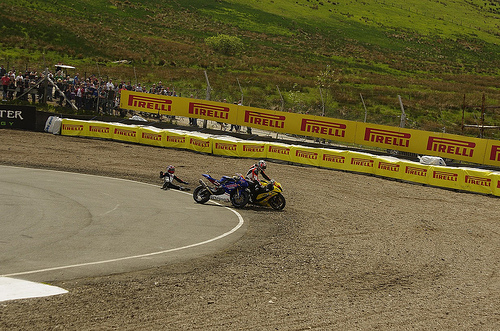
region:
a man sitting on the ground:
[157, 149, 193, 196]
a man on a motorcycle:
[240, 152, 282, 209]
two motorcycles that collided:
[188, 173, 263, 216]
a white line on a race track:
[83, 237, 219, 285]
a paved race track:
[0, 168, 117, 280]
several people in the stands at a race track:
[16, 55, 121, 111]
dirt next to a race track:
[196, 234, 431, 300]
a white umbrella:
[54, 58, 81, 75]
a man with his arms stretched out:
[152, 161, 191, 184]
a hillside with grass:
[183, 25, 444, 69]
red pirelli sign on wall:
[120, 87, 180, 116]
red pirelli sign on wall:
[178, 97, 228, 127]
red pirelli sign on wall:
[238, 102, 283, 129]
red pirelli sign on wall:
[296, 110, 353, 140]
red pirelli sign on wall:
[363, 124, 409, 149]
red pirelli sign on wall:
[425, 126, 471, 159]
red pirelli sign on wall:
[489, 145, 498, 157]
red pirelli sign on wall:
[350, 151, 377, 170]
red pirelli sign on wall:
[300, 151, 319, 166]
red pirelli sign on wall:
[165, 131, 183, 147]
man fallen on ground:
[157, 158, 192, 195]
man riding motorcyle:
[243, 153, 270, 195]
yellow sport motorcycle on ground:
[237, 173, 285, 208]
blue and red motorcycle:
[187, 165, 249, 207]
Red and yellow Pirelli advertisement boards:
[117, 88, 499, 168]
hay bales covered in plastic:
[57, 116, 498, 200]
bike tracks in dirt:
[50, 216, 440, 301]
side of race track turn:
[2, 155, 254, 300]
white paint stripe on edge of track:
[2, 155, 245, 288]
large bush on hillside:
[205, 31, 245, 54]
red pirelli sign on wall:
[252, 113, 279, 136]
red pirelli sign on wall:
[355, 109, 412, 144]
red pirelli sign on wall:
[431, 171, 459, 186]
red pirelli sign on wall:
[380, 164, 402, 176]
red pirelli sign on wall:
[295, 147, 325, 162]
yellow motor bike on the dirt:
[237, 153, 304, 218]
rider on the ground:
[137, 158, 189, 195]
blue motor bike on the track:
[186, 165, 251, 214]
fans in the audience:
[4, 60, 132, 118]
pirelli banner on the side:
[240, 105, 292, 133]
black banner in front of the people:
[2, 105, 37, 130]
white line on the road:
[54, 248, 112, 278]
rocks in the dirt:
[254, 292, 285, 309]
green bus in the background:
[199, 28, 247, 66]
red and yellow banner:
[130, 90, 433, 148]